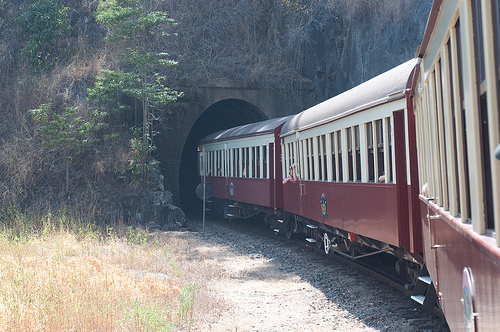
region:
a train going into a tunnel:
[171, 41, 493, 311]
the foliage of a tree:
[105, 3, 183, 106]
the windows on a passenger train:
[199, 145, 224, 175]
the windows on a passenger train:
[220, 146, 262, 176]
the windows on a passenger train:
[278, 138, 320, 180]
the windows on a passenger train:
[328, 131, 370, 181]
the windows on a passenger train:
[413, 42, 476, 210]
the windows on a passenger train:
[281, 127, 395, 185]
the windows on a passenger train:
[198, 145, 268, 184]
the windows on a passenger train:
[421, 14, 498, 249]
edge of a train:
[380, 123, 404, 151]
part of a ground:
[253, 264, 282, 296]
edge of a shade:
[286, 262, 309, 309]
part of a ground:
[133, 250, 177, 280]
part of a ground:
[272, 276, 297, 308]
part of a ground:
[233, 263, 265, 309]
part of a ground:
[245, 263, 272, 313]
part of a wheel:
[352, 252, 382, 291]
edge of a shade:
[254, 250, 277, 296]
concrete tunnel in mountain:
[179, 95, 279, 220]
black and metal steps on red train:
[411, 263, 435, 305]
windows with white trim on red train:
[359, 116, 389, 187]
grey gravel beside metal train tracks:
[319, 252, 360, 289]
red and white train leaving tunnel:
[181, 109, 290, 221]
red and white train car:
[202, 114, 286, 221]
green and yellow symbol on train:
[317, 189, 329, 219]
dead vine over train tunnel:
[146, 34, 312, 110]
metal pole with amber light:
[193, 142, 210, 235]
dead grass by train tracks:
[10, 232, 277, 269]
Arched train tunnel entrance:
[167, 98, 282, 220]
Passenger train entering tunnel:
[192, 0, 497, 328]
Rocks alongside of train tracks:
[195, 220, 415, 330]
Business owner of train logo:
[310, 190, 335, 216]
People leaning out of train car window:
[280, 160, 300, 185]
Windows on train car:
[340, 125, 362, 185]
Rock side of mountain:
[6, 5, 438, 230]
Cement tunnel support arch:
[135, 79, 288, 226]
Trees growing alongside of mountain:
[22, 4, 177, 230]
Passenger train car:
[194, 111, 286, 233]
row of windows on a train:
[290, 136, 381, 180]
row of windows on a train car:
[203, 140, 280, 180]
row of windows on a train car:
[420, 80, 494, 205]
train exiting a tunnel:
[149, 54, 320, 244]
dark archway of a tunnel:
[157, 85, 278, 227]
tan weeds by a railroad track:
[41, 234, 191, 316]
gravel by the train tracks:
[246, 224, 336, 330]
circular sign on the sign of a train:
[316, 193, 333, 218]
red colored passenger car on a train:
[281, 102, 413, 247]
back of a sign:
[196, 163, 217, 232]